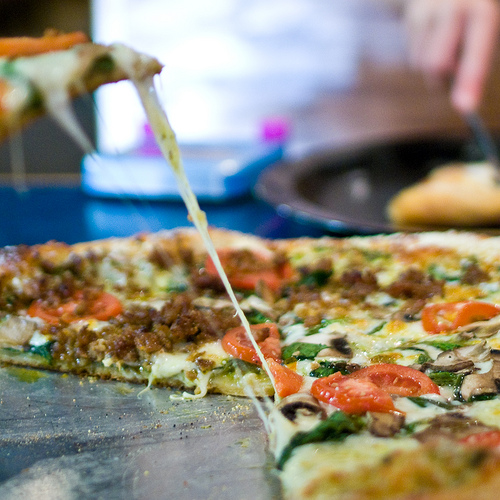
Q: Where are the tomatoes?
A: On pizza.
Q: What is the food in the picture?
A: Pizza.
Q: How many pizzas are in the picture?
A: One.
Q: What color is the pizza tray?
A: Silver.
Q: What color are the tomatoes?
A: Red.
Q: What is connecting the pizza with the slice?
A: Cheese.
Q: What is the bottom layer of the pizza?
A: Crust.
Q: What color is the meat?
A: Brown.